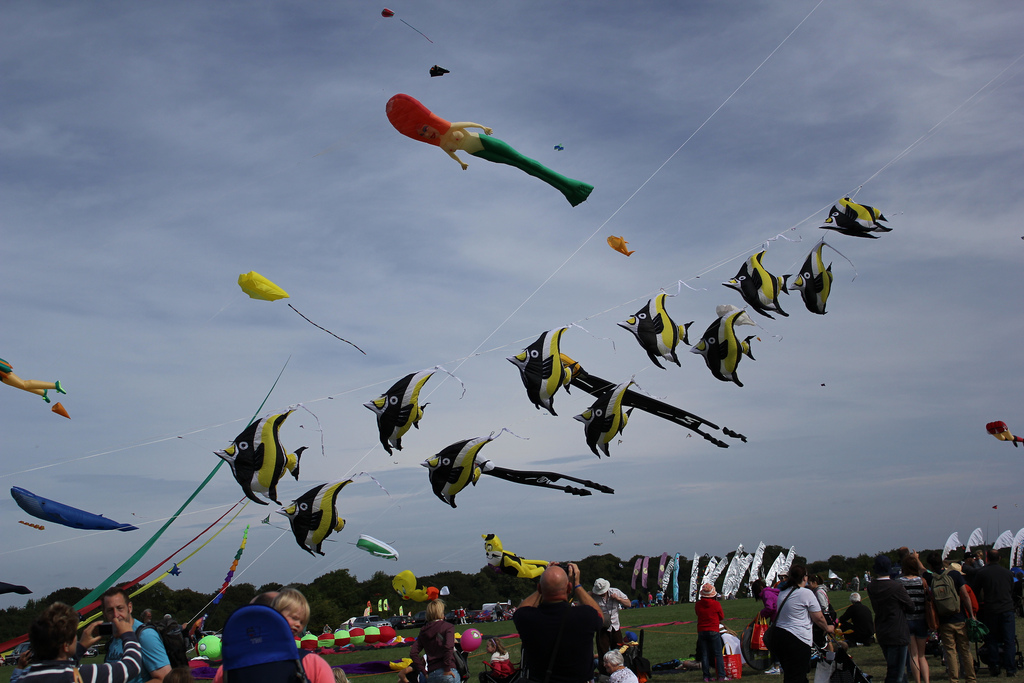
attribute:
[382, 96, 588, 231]
mermaid kite — red, beige, green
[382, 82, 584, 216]
kite — large, colorful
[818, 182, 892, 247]
kite — white, large, blue, yellow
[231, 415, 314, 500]
kite — yellow, large, blue, white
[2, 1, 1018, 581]
sky — blue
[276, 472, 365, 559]
kite — white, large, blue, yellow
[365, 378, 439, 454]
kite — yellow, large, blue, white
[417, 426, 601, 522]
kite — white, large, blue, yellow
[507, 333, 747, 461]
kite — yellow, large, blue, white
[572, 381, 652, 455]
kite — white, large, blue, yellow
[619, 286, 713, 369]
kite — yellow, large, blue, white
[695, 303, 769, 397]
kite — white, large, blue, yellow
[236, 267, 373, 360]
kite — large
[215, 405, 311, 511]
kite — blue, yellow, white, fish shaped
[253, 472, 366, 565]
kite — blue, yellow, white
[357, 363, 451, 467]
kite — white, blue, yellow